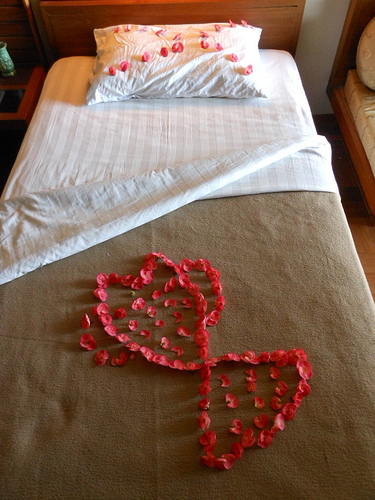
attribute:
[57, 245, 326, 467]
signs — flower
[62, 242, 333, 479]
sign — infinity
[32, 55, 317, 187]
sheets — striped, white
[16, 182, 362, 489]
bedspread — tan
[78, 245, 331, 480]
petals — flowers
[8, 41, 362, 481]
bed — size, twin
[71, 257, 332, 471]
petals — flower, pink, bottom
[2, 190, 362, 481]
blankets — brown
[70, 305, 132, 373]
petals — pink, three, flower, most left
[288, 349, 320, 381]
petals — most right, pink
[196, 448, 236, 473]
petals — bottom most, pink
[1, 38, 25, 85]
vase — green, small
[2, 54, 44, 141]
table — brown, side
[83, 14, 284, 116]
pillow — white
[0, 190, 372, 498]
comforter — brown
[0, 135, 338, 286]
sheet — white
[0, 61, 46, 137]
nightstand — brown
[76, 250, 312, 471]
flowers — red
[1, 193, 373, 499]
covering — tan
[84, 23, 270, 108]
pillow — white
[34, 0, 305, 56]
headboard — brown, wooden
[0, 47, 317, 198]
sheet — white, striped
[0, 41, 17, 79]
vase — green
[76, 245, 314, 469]
petals — pink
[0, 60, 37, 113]
tabletop — glass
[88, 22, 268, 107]
pillowcase — white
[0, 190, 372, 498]
cover — brown